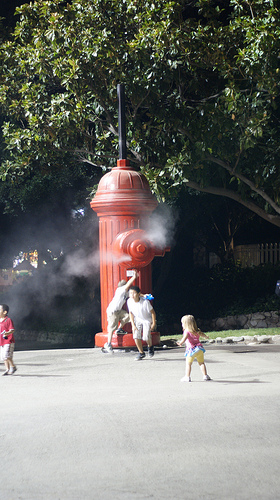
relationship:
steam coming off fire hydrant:
[45, 242, 129, 276] [85, 79, 172, 354]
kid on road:
[174, 309, 213, 385] [5, 342, 275, 488]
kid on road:
[1, 297, 20, 384] [5, 342, 275, 488]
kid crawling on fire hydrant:
[98, 278, 130, 353] [85, 79, 172, 354]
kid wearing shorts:
[174, 309, 213, 385] [184, 349, 207, 368]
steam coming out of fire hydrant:
[45, 242, 129, 276] [85, 79, 172, 354]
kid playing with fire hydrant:
[98, 278, 130, 353] [85, 79, 172, 354]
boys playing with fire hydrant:
[126, 285, 158, 360] [85, 79, 172, 354]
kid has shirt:
[1, 297, 20, 384] [2, 315, 15, 348]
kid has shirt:
[174, 309, 213, 385] [183, 328, 200, 349]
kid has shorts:
[174, 309, 213, 385] [184, 349, 207, 368]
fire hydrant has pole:
[85, 79, 172, 354] [110, 80, 131, 165]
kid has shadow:
[174, 309, 213, 385] [210, 375, 270, 391]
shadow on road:
[210, 375, 270, 391] [5, 342, 275, 488]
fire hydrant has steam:
[85, 79, 172, 354] [45, 242, 129, 276]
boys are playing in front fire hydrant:
[86, 274, 160, 369] [85, 79, 172, 354]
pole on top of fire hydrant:
[110, 80, 131, 165] [85, 79, 172, 354]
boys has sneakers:
[126, 285, 158, 360] [133, 344, 156, 362]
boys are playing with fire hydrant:
[86, 274, 160, 369] [85, 79, 172, 354]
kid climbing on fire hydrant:
[98, 278, 130, 353] [85, 79, 172, 354]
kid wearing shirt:
[1, 297, 20, 384] [2, 315, 15, 348]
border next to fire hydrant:
[205, 307, 275, 329] [85, 79, 172, 354]